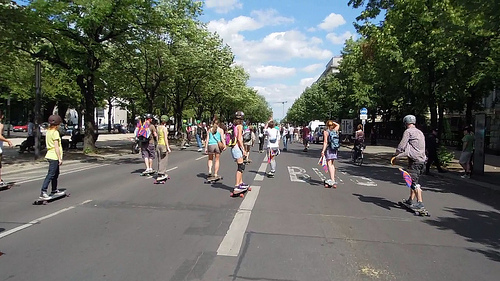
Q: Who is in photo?
A: People skateboarding in street.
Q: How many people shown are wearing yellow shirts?
A: 2.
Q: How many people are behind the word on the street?
A: 6.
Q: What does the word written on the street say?
A: Bus.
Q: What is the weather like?
A: Sunny.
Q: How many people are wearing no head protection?
A: 0.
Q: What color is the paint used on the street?
A: White.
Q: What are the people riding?
A: Skateboards.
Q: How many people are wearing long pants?
A: 2.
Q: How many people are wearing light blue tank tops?
A: 1.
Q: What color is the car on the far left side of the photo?
A: Red.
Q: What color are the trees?
A: Green.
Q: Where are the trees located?
A: Along street.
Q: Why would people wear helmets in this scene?
A: For protection.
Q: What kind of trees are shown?
A: Oak.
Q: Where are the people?
A: The street.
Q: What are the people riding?
A: Skateboards.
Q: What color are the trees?
A: Green.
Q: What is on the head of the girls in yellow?
A: Helmets.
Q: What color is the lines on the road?
A: White.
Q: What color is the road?
A: Black.